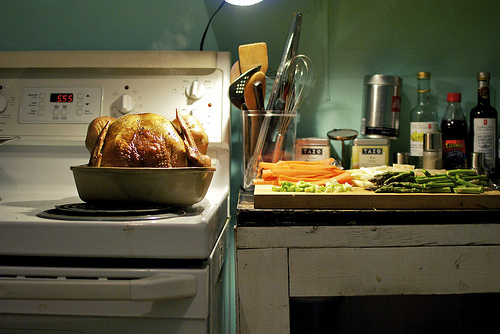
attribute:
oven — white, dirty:
[4, 215, 209, 332]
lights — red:
[28, 93, 80, 113]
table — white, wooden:
[235, 162, 499, 331]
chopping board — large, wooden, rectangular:
[244, 144, 498, 209]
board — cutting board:
[243, 175, 498, 222]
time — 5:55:
[43, 87, 71, 109]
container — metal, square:
[278, 107, 422, 161]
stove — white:
[6, 55, 226, 332]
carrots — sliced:
[253, 157, 365, 182]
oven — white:
[0, 44, 221, 331]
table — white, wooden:
[243, 195, 499, 332]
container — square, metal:
[290, 126, 343, 161]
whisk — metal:
[269, 53, 320, 163]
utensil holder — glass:
[238, 105, 298, 190]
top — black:
[234, 187, 499, 226]